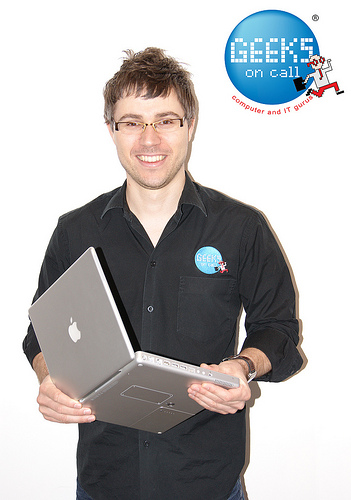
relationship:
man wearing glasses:
[24, 44, 307, 500] [113, 116, 190, 133]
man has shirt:
[24, 44, 307, 498] [13, 182, 310, 498]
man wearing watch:
[24, 44, 307, 498] [222, 352, 257, 386]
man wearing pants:
[24, 44, 307, 500] [232, 480, 249, 497]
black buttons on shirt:
[140, 253, 161, 314] [20, 181, 305, 465]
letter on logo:
[238, 35, 285, 69] [225, 10, 341, 109]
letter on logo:
[238, 35, 285, 69] [193, 241, 222, 274]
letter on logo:
[238, 35, 285, 69] [222, 22, 344, 122]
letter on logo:
[195, 253, 206, 261] [224, 4, 346, 105]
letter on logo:
[195, 253, 205, 261] [225, 10, 341, 109]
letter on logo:
[269, 69, 278, 79] [218, 7, 346, 118]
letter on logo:
[238, 35, 285, 69] [218, 7, 346, 118]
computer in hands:
[27, 245, 240, 436] [53, 385, 232, 417]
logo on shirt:
[192, 245, 234, 279] [13, 182, 310, 498]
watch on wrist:
[229, 353, 260, 388] [219, 349, 265, 391]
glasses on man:
[108, 114, 193, 133] [24, 44, 307, 498]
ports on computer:
[150, 353, 199, 386] [23, 235, 249, 453]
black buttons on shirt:
[146, 304, 155, 314] [24, 181, 310, 420]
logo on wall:
[218, 7, 346, 118] [2, 6, 95, 139]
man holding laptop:
[24, 44, 307, 500] [7, 204, 255, 447]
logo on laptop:
[66, 315, 81, 342] [28, 246, 242, 435]